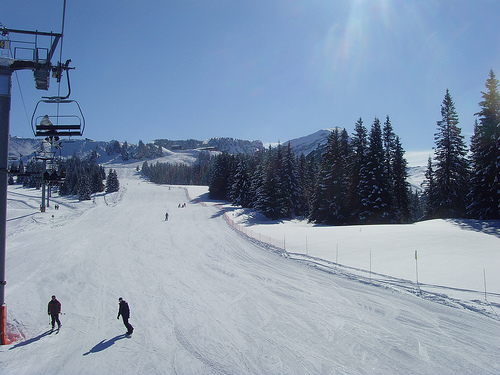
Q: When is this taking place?
A: Daytime.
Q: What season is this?
A: Winter.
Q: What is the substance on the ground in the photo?
A: Snow.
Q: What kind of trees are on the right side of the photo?
A: Evergreen trees.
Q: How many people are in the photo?
A: Three.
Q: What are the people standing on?
A: Snow slope.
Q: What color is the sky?
A: Blue and white.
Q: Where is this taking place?
A: Skiing down the slope.